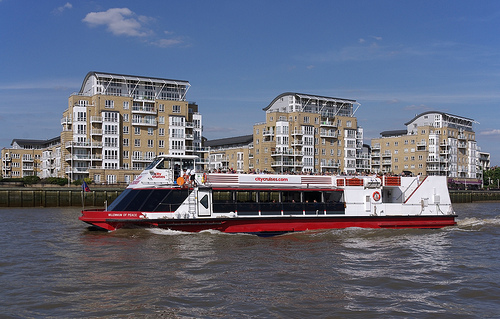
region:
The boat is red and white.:
[78, 153, 457, 233]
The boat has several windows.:
[105, 188, 191, 212]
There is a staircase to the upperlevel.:
[399, 174, 431, 202]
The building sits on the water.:
[62, 70, 207, 180]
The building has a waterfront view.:
[370, 110, 487, 182]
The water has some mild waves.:
[1, 203, 498, 316]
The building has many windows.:
[252, 91, 369, 173]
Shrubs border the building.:
[19, 174, 70, 186]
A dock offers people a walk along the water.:
[1, 185, 498, 202]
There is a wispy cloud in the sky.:
[44, 0, 199, 57]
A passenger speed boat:
[73, 152, 459, 234]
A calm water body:
[3, 180, 353, 315]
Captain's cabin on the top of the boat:
[123, 145, 210, 185]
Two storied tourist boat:
[86, 143, 476, 230]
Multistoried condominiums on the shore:
[2, 67, 499, 199]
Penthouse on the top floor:
[82, 69, 193, 111]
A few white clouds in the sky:
[15, 1, 495, 121]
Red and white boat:
[78, 150, 465, 237]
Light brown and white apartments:
[62, 68, 207, 178]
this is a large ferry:
[52, 118, 484, 285]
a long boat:
[74, 135, 462, 264]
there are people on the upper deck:
[204, 159, 426, 196]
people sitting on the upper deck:
[195, 148, 421, 192]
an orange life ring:
[364, 188, 386, 205]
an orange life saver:
[362, 185, 391, 203]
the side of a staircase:
[389, 159, 454, 213]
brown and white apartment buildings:
[19, 44, 489, 185]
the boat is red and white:
[63, 148, 485, 265]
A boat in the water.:
[76, 151, 458, 230]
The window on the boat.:
[111, 187, 190, 211]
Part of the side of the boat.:
[422, 182, 441, 199]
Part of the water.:
[92, 269, 134, 294]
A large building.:
[60, 75, 207, 185]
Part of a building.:
[257, 129, 273, 161]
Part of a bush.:
[485, 165, 499, 189]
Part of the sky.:
[326, 54, 384, 86]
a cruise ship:
[83, 143, 461, 239]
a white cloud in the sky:
[79, 8, 184, 53]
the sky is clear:
[217, 1, 296, 68]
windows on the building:
[100, 112, 119, 138]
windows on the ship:
[224, 187, 307, 212]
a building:
[376, 117, 473, 175]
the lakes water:
[208, 241, 360, 311]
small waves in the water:
[161, 282, 231, 309]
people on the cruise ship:
[186, 164, 198, 184]